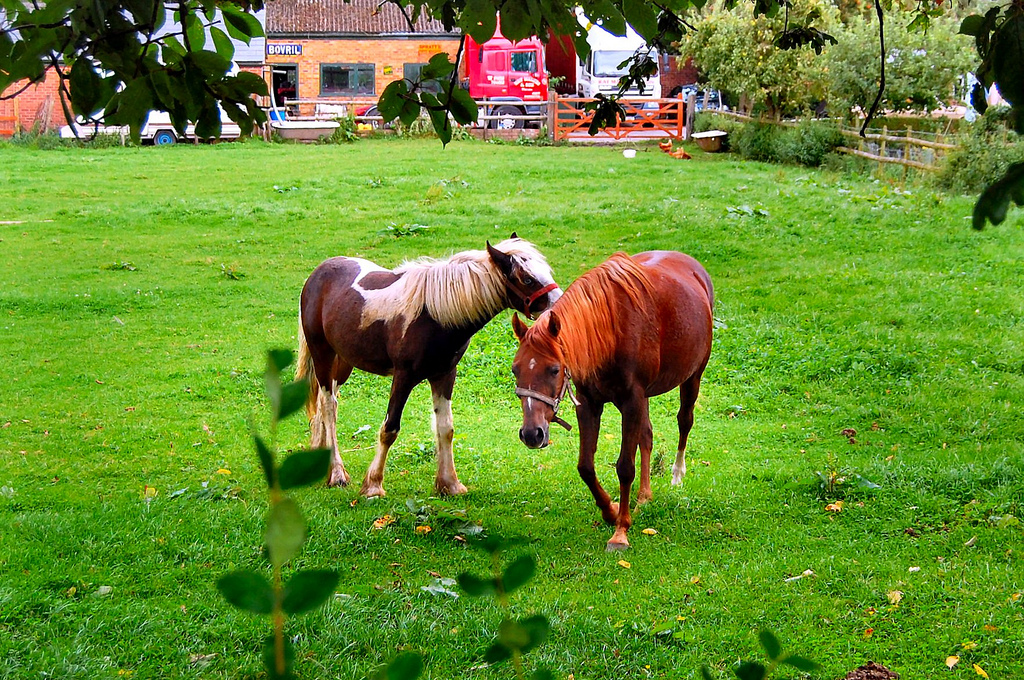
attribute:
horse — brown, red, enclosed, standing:
[511, 239, 720, 552]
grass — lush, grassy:
[4, 135, 1020, 679]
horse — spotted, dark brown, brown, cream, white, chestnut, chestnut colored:
[283, 230, 564, 508]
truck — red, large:
[353, 21, 551, 150]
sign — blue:
[267, 42, 306, 61]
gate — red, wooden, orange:
[548, 90, 691, 145]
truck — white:
[575, 43, 661, 122]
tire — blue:
[148, 130, 179, 149]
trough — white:
[270, 117, 341, 146]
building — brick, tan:
[263, 11, 472, 118]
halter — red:
[515, 283, 566, 316]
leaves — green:
[372, 83, 411, 123]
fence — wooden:
[279, 98, 561, 138]